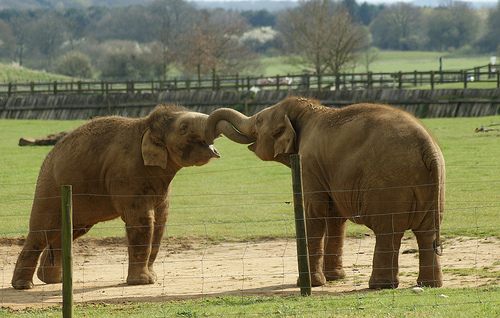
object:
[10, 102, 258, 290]
elephant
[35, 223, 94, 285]
legs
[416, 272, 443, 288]
feet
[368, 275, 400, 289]
feet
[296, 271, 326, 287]
feet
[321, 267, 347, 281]
feet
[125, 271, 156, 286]
feet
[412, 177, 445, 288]
legs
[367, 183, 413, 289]
legs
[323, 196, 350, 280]
legs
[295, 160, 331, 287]
legs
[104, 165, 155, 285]
legs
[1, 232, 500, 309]
patch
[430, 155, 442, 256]
tail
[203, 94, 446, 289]
elephant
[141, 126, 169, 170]
elephant ear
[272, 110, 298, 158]
ear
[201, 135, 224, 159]
mouths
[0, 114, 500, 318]
ground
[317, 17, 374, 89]
trees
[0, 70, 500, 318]
pen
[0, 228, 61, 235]
wire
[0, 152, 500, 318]
fencing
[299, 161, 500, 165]
wire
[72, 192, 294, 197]
wire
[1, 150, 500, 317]
front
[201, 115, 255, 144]
trunk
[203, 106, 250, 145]
trunk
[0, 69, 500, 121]
fence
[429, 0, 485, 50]
trees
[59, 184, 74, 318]
fence post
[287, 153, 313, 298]
fence post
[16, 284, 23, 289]
toe nails